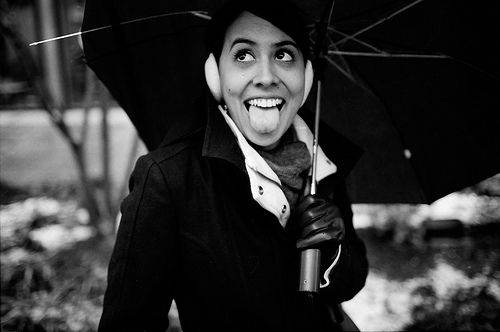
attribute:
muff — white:
[199, 49, 224, 107]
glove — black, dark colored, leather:
[288, 192, 347, 256]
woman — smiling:
[97, 3, 372, 332]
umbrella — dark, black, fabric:
[80, 2, 498, 296]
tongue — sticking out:
[247, 102, 283, 139]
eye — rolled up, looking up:
[229, 46, 261, 68]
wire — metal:
[22, 0, 182, 52]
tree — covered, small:
[2, 2, 144, 267]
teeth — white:
[246, 96, 289, 112]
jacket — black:
[98, 107, 372, 332]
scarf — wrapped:
[238, 121, 318, 244]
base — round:
[297, 231, 320, 301]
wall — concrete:
[3, 99, 152, 198]